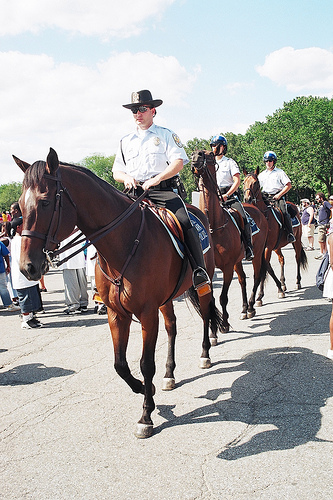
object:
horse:
[242, 165, 308, 308]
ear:
[11, 154, 31, 174]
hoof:
[133, 420, 153, 439]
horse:
[190, 148, 269, 345]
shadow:
[217, 305, 333, 345]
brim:
[146, 99, 163, 105]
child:
[10, 211, 42, 330]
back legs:
[158, 299, 186, 390]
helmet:
[209, 134, 227, 155]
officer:
[257, 150, 296, 242]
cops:
[112, 89, 212, 297]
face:
[17, 164, 77, 281]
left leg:
[134, 309, 159, 438]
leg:
[199, 294, 213, 368]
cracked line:
[195, 309, 333, 499]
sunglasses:
[131, 104, 148, 114]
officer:
[112, 90, 212, 299]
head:
[12, 147, 76, 282]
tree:
[0, 95, 333, 214]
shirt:
[213, 156, 240, 192]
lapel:
[148, 123, 157, 134]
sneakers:
[21, 314, 43, 330]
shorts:
[15, 284, 42, 313]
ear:
[43, 147, 63, 176]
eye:
[41, 197, 49, 208]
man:
[300, 198, 318, 251]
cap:
[300, 199, 310, 204]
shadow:
[40, 318, 108, 329]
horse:
[12, 146, 233, 438]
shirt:
[111, 122, 190, 191]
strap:
[49, 184, 149, 258]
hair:
[22, 160, 46, 187]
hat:
[122, 90, 163, 110]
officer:
[210, 134, 255, 260]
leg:
[106, 306, 155, 395]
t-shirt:
[9, 234, 39, 290]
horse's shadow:
[151, 347, 332, 462]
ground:
[0, 234, 333, 499]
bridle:
[21, 168, 77, 251]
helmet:
[263, 150, 277, 164]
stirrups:
[192, 265, 211, 290]